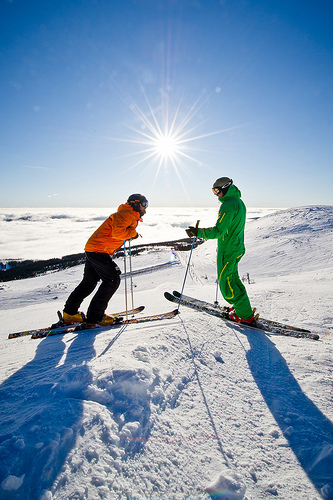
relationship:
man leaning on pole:
[61, 193, 149, 328] [168, 220, 202, 318]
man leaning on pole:
[61, 193, 149, 328] [127, 238, 136, 325]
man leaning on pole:
[185, 176, 254, 325] [119, 238, 126, 323]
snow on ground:
[270, 239, 312, 275] [15, 279, 46, 307]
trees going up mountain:
[1, 254, 78, 281] [2, 203, 331, 295]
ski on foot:
[164, 292, 319, 340] [220, 309, 255, 324]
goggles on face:
[137, 198, 149, 207] [135, 194, 148, 214]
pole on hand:
[157, 223, 221, 281] [162, 218, 216, 231]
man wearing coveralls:
[185, 177, 252, 323] [195, 186, 252, 318]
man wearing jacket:
[61, 193, 149, 328] [85, 201, 141, 253]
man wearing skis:
[185, 177, 252, 323] [165, 290, 319, 339]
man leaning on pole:
[61, 193, 149, 328] [123, 240, 128, 322]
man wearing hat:
[33, 181, 147, 304] [127, 183, 163, 210]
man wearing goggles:
[185, 176, 254, 325] [209, 178, 236, 196]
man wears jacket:
[61, 193, 149, 328] [82, 199, 146, 257]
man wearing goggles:
[61, 193, 149, 328] [127, 197, 148, 208]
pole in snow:
[123, 240, 128, 322] [10, 353, 305, 498]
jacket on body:
[82, 199, 146, 257] [83, 202, 140, 254]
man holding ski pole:
[185, 176, 254, 325] [173, 216, 200, 311]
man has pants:
[61, 193, 149, 328] [61, 247, 124, 326]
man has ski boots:
[61, 193, 149, 328] [224, 303, 252, 325]